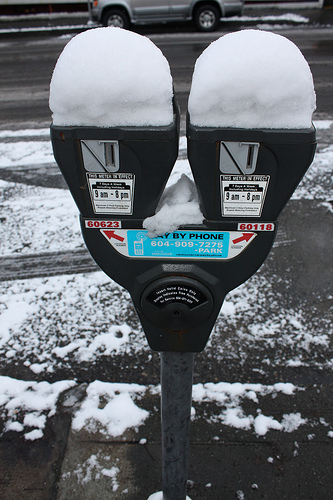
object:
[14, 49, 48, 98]
people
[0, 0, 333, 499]
outdoors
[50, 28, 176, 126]
snow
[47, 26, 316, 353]
parking meter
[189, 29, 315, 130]
snow